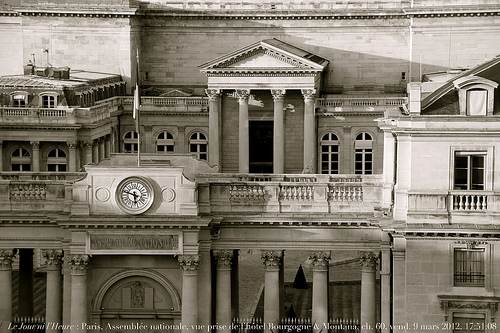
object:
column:
[205, 88, 224, 172]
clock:
[115, 176, 156, 215]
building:
[0, 0, 499, 333]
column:
[213, 249, 233, 333]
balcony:
[0, 170, 382, 218]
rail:
[198, 173, 384, 216]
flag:
[133, 45, 142, 167]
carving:
[94, 238, 177, 247]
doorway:
[91, 268, 181, 333]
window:
[11, 93, 26, 115]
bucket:
[25, 64, 35, 75]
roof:
[0, 69, 121, 90]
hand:
[124, 190, 139, 203]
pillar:
[235, 89, 250, 173]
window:
[42, 94, 56, 108]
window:
[454, 151, 486, 210]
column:
[261, 251, 282, 333]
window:
[466, 88, 489, 116]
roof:
[196, 38, 330, 72]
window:
[319, 132, 340, 174]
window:
[354, 132, 374, 175]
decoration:
[261, 249, 283, 271]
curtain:
[467, 90, 487, 115]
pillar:
[309, 250, 333, 332]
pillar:
[270, 89, 286, 174]